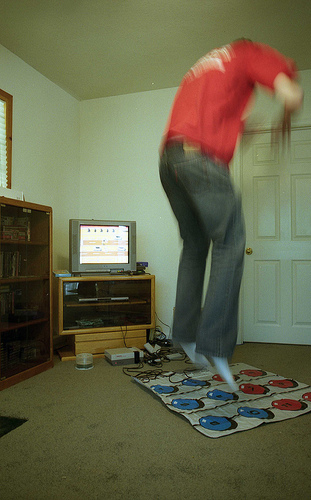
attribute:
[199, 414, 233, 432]
circle — blue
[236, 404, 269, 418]
circle — blue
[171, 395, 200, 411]
circle — blue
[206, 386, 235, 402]
circle — blue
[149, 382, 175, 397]
circle — blue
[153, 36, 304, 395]
man — jumping, playing video game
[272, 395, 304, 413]
button — red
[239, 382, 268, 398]
button — red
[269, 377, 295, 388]
button — red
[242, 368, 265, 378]
button — red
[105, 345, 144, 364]
video game console — original nintendo, nintendo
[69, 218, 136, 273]
tv — gray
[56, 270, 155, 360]
cabinet — wood, wooden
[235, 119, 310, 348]
door — white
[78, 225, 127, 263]
television screen — illuminated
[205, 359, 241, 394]
sock — white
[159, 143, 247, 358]
jeans — blue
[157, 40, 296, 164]
t-shirt — red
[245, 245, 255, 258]
door knob — golden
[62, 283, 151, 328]
door — glass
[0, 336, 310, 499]
carpet — on the floor, beige